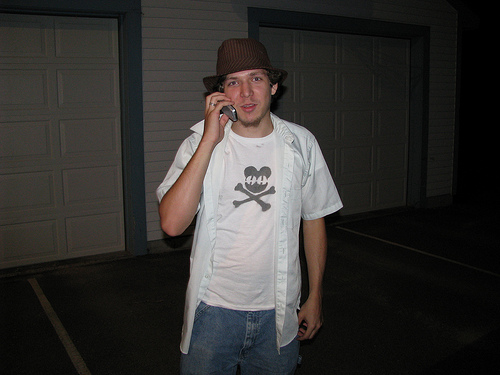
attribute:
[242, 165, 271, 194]
skull — silver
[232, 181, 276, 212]
crossbone — silver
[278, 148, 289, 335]
seam — white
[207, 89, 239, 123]
phone — silver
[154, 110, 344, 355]
shirt — white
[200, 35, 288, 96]
hat — brown, striped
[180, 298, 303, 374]
jeans — blue, denim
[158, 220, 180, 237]
elbow — white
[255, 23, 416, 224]
door — white, closed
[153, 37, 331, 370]
man — standing, talking, young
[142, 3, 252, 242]
wall — white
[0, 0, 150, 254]
frame — green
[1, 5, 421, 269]
doors — white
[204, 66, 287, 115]
hair — dark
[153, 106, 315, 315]
tshirt — white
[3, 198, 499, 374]
parking lot — paved